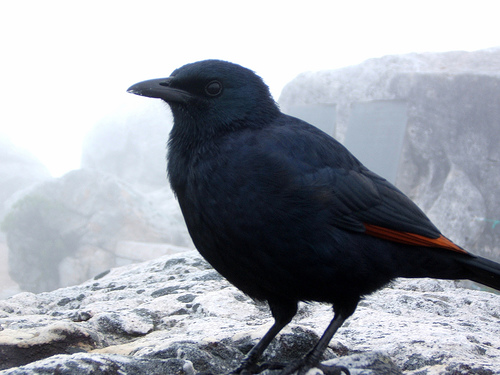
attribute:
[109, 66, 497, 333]
bird — blue, black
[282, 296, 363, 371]
leg — black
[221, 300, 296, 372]
leg — black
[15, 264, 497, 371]
rocks — light colored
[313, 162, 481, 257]
wings — red, black, feathered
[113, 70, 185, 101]
beak — black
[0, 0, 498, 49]
sky — clear, bright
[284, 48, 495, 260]
mountain — grey, craggy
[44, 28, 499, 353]
blackbird — black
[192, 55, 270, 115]
eye — black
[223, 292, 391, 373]
legs — black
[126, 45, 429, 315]
bird — black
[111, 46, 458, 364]
bird — black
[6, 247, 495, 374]
ground —  rocky,  snowy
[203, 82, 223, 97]
eye — beady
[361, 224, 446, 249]
feather — red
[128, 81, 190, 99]
beak — black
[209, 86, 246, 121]
eye — round, black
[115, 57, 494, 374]
bird — one, black, small, dark, one black bird 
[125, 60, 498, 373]
black bird — small, in profile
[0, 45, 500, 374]
rocks — craggy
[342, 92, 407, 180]
carved surface — smooth, rock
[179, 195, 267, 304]
belly — black, feathered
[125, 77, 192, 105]
beak —   black 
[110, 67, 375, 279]
blackbird — black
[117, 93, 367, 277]
blackbird — black